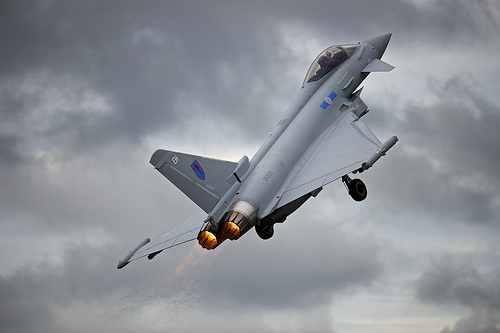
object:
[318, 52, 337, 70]
man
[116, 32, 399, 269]
plane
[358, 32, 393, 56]
plane's nose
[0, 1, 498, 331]
sky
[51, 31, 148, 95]
clouds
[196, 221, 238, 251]
lights